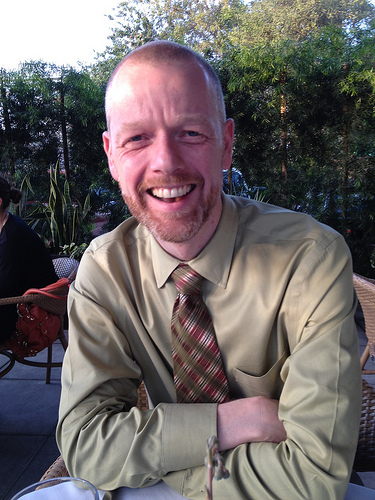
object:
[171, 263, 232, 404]
tie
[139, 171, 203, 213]
mouth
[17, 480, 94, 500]
napkin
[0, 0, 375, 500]
picture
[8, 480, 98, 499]
glass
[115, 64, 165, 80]
wall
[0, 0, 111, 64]
day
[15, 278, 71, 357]
bag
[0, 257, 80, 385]
chair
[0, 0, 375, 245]
trees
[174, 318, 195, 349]
green plaid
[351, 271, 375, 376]
chair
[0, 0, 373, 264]
greenery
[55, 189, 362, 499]
dress shirt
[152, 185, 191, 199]
teeth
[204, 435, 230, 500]
rope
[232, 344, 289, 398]
pocket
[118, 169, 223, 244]
beard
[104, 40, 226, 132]
hair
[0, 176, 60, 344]
woman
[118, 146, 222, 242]
smile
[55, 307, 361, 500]
arms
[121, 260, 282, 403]
chest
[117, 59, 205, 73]
hairline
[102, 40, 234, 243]
head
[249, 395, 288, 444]
hand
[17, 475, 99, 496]
glass rim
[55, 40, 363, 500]
man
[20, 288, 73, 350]
back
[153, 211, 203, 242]
chin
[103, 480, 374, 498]
table